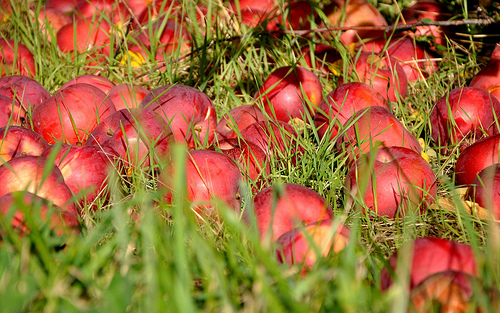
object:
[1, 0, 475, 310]
harvested apples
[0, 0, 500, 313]
field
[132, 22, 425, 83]
stick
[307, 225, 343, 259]
yellow spots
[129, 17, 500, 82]
branch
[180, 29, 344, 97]
shadow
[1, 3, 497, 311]
ground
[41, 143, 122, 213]
apple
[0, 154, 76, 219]
apple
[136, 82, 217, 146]
apple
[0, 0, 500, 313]
floor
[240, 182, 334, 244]
apple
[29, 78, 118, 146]
apple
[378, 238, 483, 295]
apple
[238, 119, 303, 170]
apple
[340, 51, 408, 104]
apple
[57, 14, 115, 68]
apple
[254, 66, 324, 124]
apple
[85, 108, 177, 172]
apple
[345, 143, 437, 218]
apple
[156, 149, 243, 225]
apple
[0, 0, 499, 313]
grass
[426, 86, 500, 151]
apple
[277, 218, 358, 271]
apple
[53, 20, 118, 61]
apples